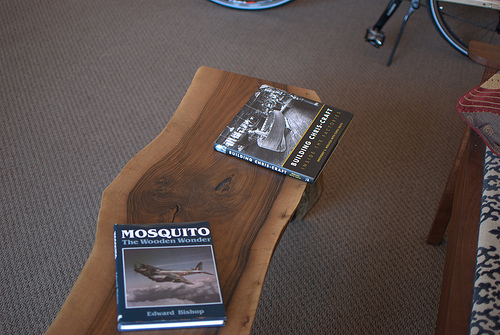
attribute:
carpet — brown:
[45, 251, 67, 274]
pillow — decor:
[453, 67, 495, 168]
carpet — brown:
[2, 0, 493, 333]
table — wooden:
[106, 66, 236, 216]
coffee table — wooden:
[70, 45, 317, 330]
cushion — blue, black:
[472, 119, 499, 334]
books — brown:
[218, 54, 365, 208]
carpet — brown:
[17, 160, 79, 240]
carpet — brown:
[0, 1, 431, 330]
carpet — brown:
[10, 118, 64, 185]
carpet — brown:
[373, 160, 400, 187]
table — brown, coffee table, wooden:
[42, 63, 327, 331]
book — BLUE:
[113, 221, 228, 330]